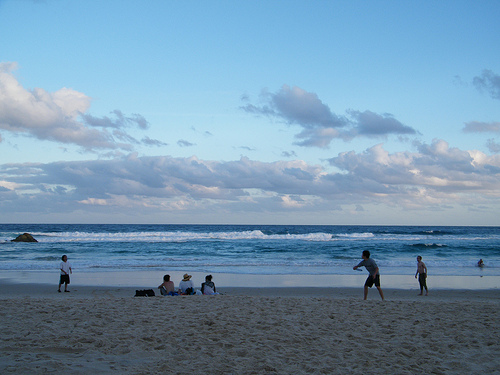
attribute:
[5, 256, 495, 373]
beach — sandy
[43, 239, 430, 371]
beach — sandy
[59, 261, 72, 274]
shirt — white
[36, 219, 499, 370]
beach — sandy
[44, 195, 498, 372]
beach — sandy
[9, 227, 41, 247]
stone — big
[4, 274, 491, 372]
beach — sandy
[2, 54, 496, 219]
clouds — white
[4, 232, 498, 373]
beach — sandy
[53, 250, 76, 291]
man — young